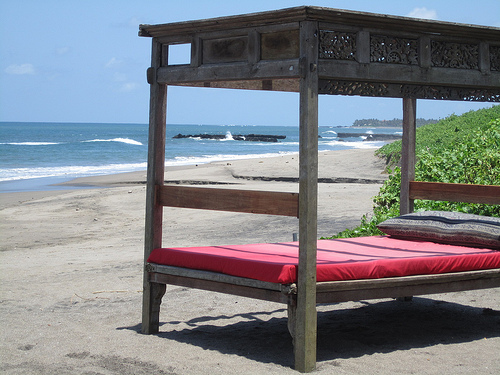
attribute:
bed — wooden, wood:
[138, 7, 499, 373]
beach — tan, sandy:
[4, 147, 497, 374]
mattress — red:
[146, 234, 497, 276]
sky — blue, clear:
[1, 1, 497, 121]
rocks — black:
[170, 131, 292, 144]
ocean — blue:
[3, 122, 427, 186]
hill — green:
[364, 104, 499, 228]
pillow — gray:
[375, 207, 499, 253]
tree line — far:
[352, 115, 448, 131]